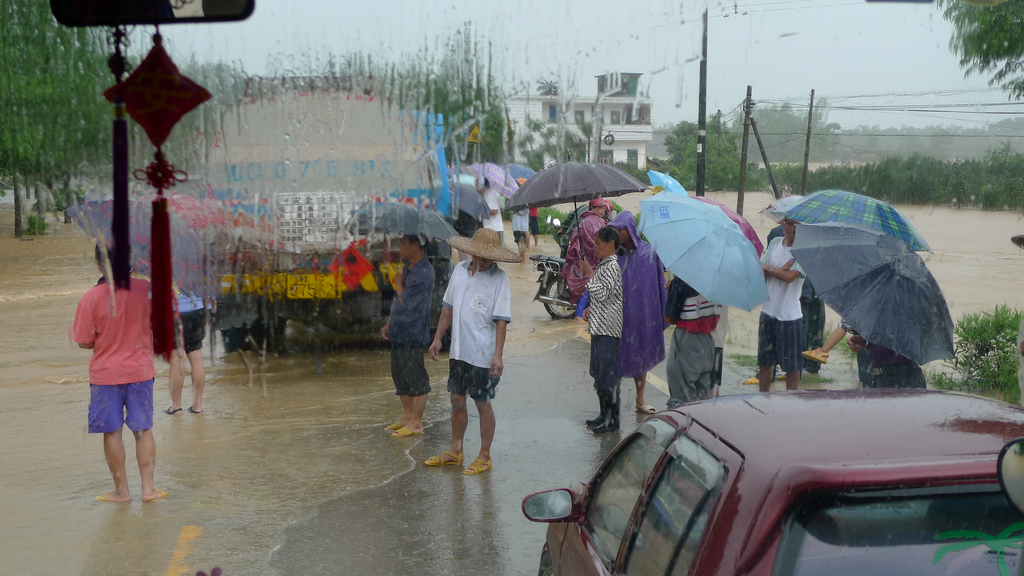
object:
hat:
[444, 228, 523, 263]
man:
[424, 228, 523, 475]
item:
[102, 31, 212, 363]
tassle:
[106, 25, 131, 291]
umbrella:
[770, 190, 932, 254]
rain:
[0, 0, 1024, 576]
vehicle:
[521, 388, 1020, 576]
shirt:
[584, 254, 623, 338]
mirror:
[521, 488, 578, 522]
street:
[0, 326, 770, 575]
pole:
[736, 86, 752, 218]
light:
[742, 98, 756, 114]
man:
[380, 233, 435, 437]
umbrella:
[343, 205, 461, 241]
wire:
[747, 100, 1023, 111]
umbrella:
[504, 155, 654, 278]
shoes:
[425, 451, 493, 474]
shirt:
[72, 277, 155, 385]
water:
[2, 188, 1021, 576]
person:
[559, 198, 609, 323]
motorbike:
[529, 254, 578, 320]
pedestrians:
[580, 227, 624, 434]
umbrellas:
[638, 190, 770, 312]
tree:
[0, 1, 118, 240]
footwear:
[384, 419, 423, 437]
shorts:
[391, 341, 432, 396]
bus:
[200, 90, 450, 353]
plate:
[287, 273, 344, 299]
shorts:
[88, 377, 156, 434]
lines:
[745, 103, 1022, 139]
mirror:
[49, 0, 255, 28]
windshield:
[759, 470, 1024, 576]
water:
[742, 436, 1022, 573]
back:
[529, 253, 565, 269]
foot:
[95, 491, 131, 503]